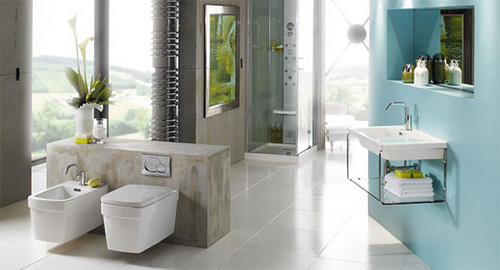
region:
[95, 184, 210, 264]
toilet in the bathroom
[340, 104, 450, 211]
sink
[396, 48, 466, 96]
bottles in front of a mirror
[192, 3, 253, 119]
artwork in the bathroom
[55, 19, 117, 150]
plant on the ledge in the bathrrom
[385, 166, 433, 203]
towels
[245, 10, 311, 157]
shower in the back of the bathrom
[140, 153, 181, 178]
toilet flush lever on wall above toilet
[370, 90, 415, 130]
faucet on the sink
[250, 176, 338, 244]
white tile on the bathroom floor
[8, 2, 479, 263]
pristine bathroom in house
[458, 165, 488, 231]
sky blue wall with sink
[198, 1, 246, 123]
portrait with silver frame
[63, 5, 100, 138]
lilies with white vase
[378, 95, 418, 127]
stainless steel faucet for sink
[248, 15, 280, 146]
clear glass shower door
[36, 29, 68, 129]
long clear window looking outside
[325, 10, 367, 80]
decoration on window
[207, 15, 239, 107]
portraits with lots of green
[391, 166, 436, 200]
white towels stacked on shelf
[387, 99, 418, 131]
silver faucet on sink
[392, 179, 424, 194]
towels underneath the sink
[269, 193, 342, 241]
part of the ceramic floor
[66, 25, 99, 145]
a plant on island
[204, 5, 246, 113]
framed picture on wall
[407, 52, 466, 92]
several toiletries on shelf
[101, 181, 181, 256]
a white contemporary toilet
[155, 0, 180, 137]
a tall silver pole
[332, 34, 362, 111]
a window in bathroom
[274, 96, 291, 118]
white shelf in shower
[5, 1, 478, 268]
A bathroom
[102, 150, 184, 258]
A toilet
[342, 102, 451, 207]
A white sink against the wall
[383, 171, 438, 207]
A stack of white towels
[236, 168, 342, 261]
Large white tiles on the floor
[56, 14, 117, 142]
A flowering plant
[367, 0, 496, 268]
A light blue colored wall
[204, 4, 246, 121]
A picture hanging on the wall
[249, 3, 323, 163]
A stand up shower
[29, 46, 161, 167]
A view of the countryside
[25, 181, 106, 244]
a square mounted deep sink of the tan unit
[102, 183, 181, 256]
a square mounted deep toilet of the tan unit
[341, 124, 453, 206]
a square mounted sink on the wall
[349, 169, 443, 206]
the glass shelf under the sink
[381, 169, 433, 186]
the folded towel on the shelf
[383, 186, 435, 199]
the folded towel on the shelf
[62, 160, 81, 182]
the silver faucet of the sink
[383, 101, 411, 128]
the silver faucet of the sink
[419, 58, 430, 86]
a bottle of white lotion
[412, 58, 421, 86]
a bottle of white lotion